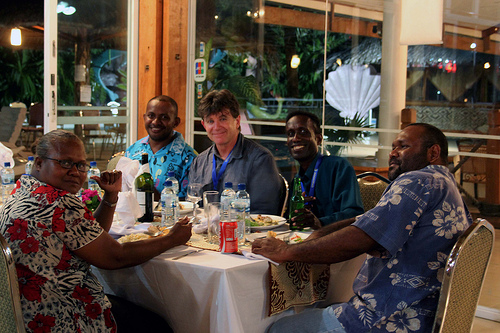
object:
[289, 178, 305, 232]
bottle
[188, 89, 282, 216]
male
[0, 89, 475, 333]
people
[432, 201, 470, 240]
white flowers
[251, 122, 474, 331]
man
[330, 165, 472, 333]
blue shirt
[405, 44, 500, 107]
window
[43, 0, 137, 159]
window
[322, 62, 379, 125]
decor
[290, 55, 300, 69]
light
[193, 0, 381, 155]
windows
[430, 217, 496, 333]
chair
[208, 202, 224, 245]
glass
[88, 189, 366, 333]
table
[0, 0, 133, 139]
door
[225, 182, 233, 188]
cap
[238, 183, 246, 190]
cap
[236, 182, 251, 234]
bottle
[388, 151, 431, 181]
facial hair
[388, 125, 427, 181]
face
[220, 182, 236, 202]
bottles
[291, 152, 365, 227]
shirts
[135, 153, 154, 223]
bottle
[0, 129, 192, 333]
woman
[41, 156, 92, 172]
glasses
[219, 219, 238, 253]
can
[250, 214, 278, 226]
food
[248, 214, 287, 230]
plate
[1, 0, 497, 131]
wall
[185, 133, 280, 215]
shirt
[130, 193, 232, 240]
middle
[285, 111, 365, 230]
man